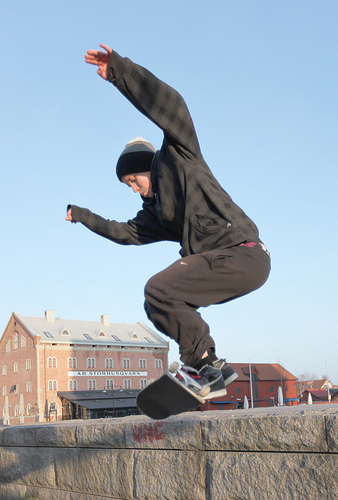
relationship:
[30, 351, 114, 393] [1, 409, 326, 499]
wall has pattern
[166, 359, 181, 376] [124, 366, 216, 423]
wheel on skateboard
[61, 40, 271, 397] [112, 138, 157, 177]
boy wearing beanie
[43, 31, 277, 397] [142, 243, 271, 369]
boy in black pants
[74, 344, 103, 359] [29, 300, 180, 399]
window in building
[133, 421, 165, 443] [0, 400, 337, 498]
graffiti on rock wall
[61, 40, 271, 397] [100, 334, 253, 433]
boy performing trick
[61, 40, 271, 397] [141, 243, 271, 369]
boy wears black pants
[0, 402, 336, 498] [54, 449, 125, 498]
fence made of stone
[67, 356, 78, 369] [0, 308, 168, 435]
window on side of building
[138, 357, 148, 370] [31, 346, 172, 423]
window on side of side of building side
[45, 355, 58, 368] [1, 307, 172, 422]
window on side of side of building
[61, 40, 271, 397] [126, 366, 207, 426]
boy riding skateboard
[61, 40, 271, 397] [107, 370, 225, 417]
boy jumping skateboard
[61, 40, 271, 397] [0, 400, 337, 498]
boy near rock wall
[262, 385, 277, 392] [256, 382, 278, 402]
items on wall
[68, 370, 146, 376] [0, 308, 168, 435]
business name on building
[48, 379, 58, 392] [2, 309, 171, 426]
window on side of brick building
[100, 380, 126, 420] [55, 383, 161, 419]
street lamp in front of building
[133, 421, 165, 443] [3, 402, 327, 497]
graffiti on wall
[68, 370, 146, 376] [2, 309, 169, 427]
business name on brick building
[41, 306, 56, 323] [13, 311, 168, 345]
chimney on roof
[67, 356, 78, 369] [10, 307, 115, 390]
window on building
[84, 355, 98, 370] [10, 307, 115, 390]
window on building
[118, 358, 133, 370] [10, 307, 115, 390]
window on building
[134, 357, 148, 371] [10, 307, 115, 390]
window on building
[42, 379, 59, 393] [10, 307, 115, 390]
window on building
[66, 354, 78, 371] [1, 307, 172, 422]
window on building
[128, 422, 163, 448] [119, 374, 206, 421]
graffiti below skateboard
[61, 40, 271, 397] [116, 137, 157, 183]
boy wearing beanie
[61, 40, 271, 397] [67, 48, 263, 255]
boy wearing shirt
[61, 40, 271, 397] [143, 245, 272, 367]
boy wearing pants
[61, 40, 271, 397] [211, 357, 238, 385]
boy wearing sneakers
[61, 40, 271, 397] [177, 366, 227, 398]
boy wearing sneakers